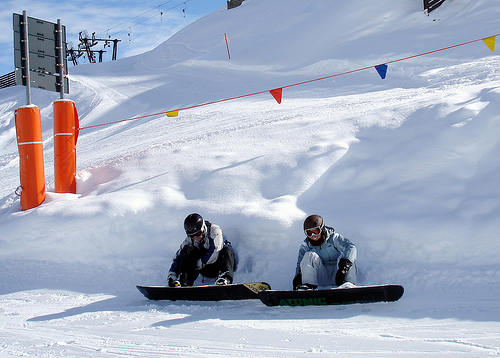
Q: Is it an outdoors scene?
A: Yes, it is outdoors.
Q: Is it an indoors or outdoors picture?
A: It is outdoors.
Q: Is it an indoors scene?
A: No, it is outdoors.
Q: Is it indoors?
A: No, it is outdoors.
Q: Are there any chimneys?
A: No, there are no chimneys.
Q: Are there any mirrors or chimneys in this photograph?
A: No, there are no chimneys or mirrors.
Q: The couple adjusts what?
A: The couple adjusts the snowboard.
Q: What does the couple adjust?
A: The couple adjusts the snowboard.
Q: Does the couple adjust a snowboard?
A: Yes, the couple adjusts a snowboard.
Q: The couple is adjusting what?
A: The couple is adjusting the snowboard.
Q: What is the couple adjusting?
A: The couple is adjusting the snowboard.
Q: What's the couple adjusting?
A: The couple is adjusting the snowboard.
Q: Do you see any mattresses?
A: No, there are no mattresses.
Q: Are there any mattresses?
A: No, there are no mattresses.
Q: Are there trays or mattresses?
A: No, there are no mattresses or trays.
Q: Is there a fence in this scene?
A: No, there are no fences.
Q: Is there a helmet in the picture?
A: Yes, there is a helmet.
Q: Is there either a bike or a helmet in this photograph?
A: Yes, there is a helmet.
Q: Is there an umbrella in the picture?
A: No, there are no umbrellas.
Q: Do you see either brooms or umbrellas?
A: No, there are no umbrellas or brooms.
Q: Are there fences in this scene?
A: No, there are no fences.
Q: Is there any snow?
A: Yes, there is snow.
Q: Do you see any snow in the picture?
A: Yes, there is snow.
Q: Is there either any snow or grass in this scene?
A: Yes, there is snow.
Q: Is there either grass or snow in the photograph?
A: Yes, there is snow.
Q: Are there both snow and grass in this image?
A: No, there is snow but no grass.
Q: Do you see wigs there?
A: No, there are no wigs.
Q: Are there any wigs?
A: No, there are no wigs.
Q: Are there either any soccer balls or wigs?
A: No, there are no wigs or soccer balls.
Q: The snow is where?
A: The snow is on the ground.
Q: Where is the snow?
A: The snow is on the ground.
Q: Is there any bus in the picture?
A: No, there are no buses.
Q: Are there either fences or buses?
A: No, there are no buses or fences.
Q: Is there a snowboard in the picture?
A: Yes, there is a snowboard.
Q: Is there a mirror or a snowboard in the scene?
A: Yes, there is a snowboard.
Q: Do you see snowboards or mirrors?
A: Yes, there is a snowboard.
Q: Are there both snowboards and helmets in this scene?
A: Yes, there are both a snowboard and a helmet.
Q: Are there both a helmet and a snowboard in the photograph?
A: Yes, there are both a snowboard and a helmet.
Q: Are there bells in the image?
A: No, there are no bells.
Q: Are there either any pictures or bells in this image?
A: No, there are no bells or pictures.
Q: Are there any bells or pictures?
A: No, there are no bells or pictures.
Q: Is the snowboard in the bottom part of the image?
A: Yes, the snowboard is in the bottom of the image.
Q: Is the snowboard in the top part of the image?
A: No, the snowboard is in the bottom of the image.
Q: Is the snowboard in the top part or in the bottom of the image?
A: The snowboard is in the bottom of the image.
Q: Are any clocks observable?
A: No, there are no clocks.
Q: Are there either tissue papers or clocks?
A: No, there are no clocks or tissue papers.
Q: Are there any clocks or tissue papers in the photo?
A: No, there are no clocks or tissue papers.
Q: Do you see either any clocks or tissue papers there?
A: No, there are no clocks or tissue papers.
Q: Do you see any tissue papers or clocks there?
A: No, there are no clocks or tissue papers.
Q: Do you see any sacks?
A: No, there are no sacks.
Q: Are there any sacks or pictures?
A: No, there are no sacks or pictures.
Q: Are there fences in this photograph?
A: No, there are no fences.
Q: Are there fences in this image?
A: No, there are no fences.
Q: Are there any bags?
A: No, there are no bags.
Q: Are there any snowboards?
A: Yes, there is a snowboard.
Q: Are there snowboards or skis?
A: Yes, there is a snowboard.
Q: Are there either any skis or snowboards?
A: Yes, there is a snowboard.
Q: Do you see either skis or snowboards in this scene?
A: Yes, there is a snowboard.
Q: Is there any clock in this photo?
A: No, there are no clocks.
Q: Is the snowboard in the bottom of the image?
A: Yes, the snowboard is in the bottom of the image.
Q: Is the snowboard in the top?
A: No, the snowboard is in the bottom of the image.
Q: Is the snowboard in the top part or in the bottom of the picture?
A: The snowboard is in the bottom of the image.